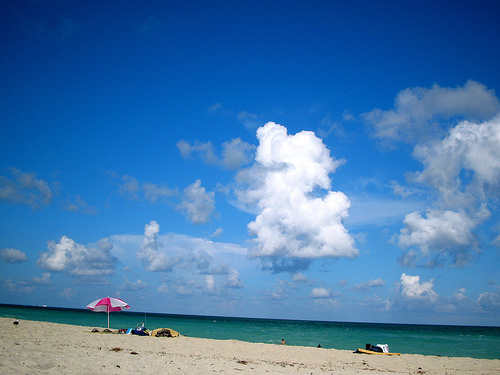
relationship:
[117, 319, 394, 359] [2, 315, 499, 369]
belongings left on sand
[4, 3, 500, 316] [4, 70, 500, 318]
sky has many clouds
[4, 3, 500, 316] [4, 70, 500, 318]
sky contains clouds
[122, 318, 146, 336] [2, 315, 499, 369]
person are lying on sand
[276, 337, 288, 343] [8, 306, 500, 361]
person in ocean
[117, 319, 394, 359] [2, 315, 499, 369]
belongings are on sand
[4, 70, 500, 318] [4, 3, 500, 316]
clouds in sky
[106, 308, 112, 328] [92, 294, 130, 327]
stick of beach umbrella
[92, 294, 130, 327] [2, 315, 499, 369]
beach umbrella in sand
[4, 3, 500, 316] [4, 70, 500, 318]
sky with some clouds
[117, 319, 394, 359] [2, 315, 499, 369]
belongings on sand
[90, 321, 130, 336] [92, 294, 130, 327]
belongings near beach umbrella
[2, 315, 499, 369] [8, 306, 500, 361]
sand near ocean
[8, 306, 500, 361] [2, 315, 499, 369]
ocean beyond sand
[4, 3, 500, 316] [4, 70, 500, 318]
sky with clouds